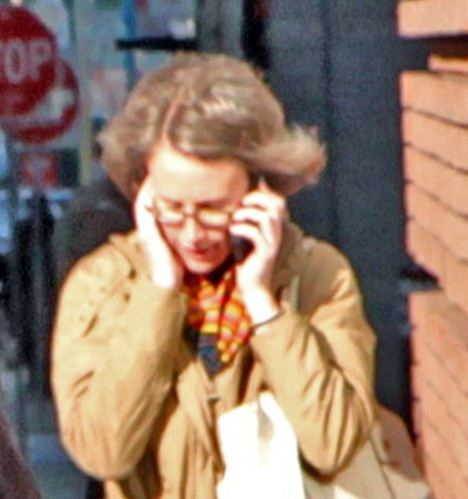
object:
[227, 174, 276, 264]
cell phone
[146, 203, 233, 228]
glasses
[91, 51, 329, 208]
hair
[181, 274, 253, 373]
scarf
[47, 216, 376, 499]
jacket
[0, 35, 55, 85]
sign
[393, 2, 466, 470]
wall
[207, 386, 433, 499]
bag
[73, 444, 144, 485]
elbow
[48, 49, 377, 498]
woman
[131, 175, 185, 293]
hand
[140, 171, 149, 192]
ear